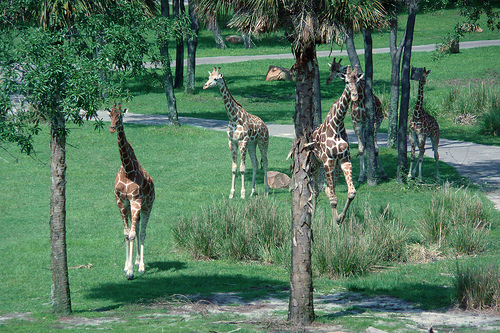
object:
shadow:
[67, 261, 488, 322]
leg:
[338, 152, 356, 215]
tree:
[0, 2, 200, 315]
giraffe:
[407, 66, 443, 184]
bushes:
[170, 176, 500, 316]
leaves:
[38, 37, 134, 100]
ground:
[0, 0, 500, 333]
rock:
[264, 171, 292, 189]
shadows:
[440, 160, 500, 191]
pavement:
[3, 86, 500, 208]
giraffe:
[325, 57, 389, 182]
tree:
[203, 1, 393, 324]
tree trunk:
[285, 66, 318, 323]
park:
[0, 1, 500, 333]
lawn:
[0, 111, 499, 333]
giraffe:
[201, 66, 268, 200]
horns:
[214, 67, 221, 72]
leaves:
[192, 2, 396, 46]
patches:
[219, 278, 498, 331]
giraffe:
[104, 99, 155, 280]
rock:
[265, 65, 295, 81]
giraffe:
[312, 64, 365, 227]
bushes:
[442, 76, 499, 135]